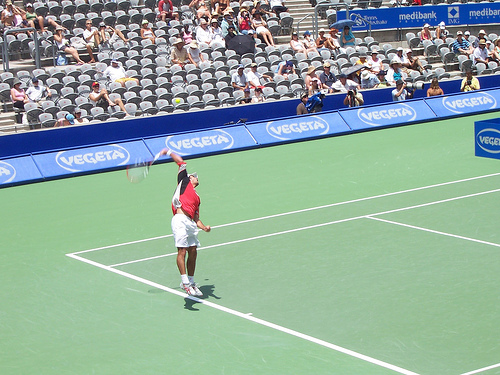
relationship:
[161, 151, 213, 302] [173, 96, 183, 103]
tennis player hitting ball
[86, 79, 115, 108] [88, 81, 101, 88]
spectator wearing hat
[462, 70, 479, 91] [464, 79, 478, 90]
man wearing shirt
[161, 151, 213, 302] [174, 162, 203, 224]
tennis player wearing shirt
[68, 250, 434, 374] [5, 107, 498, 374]
line on tennis court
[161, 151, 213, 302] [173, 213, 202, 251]
tennis player wearing shorts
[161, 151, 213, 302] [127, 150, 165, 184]
tennis player holding tennis racket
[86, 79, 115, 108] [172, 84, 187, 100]
spectator in chair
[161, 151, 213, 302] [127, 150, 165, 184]
tennis player swinging tennis racket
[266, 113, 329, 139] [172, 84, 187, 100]
advertisement sign in front of chair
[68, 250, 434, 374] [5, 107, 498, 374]
line on top of tennis court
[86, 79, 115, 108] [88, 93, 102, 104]
spectator sitting in chair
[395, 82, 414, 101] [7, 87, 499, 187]
camera man standing behind wall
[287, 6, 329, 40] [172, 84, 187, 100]
stairs next to chair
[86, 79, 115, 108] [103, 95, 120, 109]
spectator has legs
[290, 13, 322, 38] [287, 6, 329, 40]
rail next to stairs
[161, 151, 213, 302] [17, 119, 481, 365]
tennis player on court